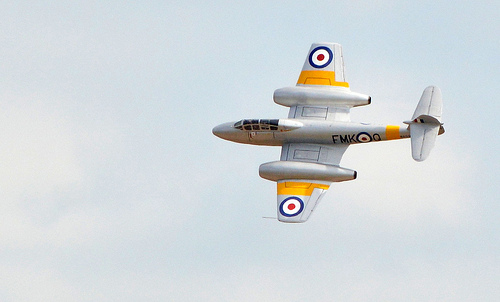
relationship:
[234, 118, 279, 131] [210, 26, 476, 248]
window on a plane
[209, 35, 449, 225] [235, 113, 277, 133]
plane has window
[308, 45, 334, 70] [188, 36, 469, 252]
circle on plane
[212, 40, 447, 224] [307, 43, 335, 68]
plane has circle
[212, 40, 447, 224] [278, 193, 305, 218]
plane has circle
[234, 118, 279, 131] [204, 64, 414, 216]
window on airplane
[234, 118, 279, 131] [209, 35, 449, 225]
window on plane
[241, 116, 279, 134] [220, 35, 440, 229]
window on plane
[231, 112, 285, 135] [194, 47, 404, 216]
plane window on plane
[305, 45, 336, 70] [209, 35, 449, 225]
circle on plane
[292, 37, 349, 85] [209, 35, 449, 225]
wing on plane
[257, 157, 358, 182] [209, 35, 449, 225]
engine on plane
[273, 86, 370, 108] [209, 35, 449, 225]
engine on plane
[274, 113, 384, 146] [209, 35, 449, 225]
middle on plane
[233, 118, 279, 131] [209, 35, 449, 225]
glass on plane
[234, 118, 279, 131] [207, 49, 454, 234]
window on plane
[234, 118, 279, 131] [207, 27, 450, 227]
window on airplane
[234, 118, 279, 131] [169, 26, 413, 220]
window on airplane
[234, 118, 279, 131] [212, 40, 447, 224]
window on plane